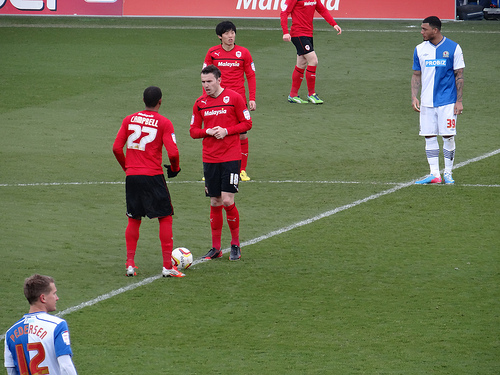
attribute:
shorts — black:
[121, 167, 175, 221]